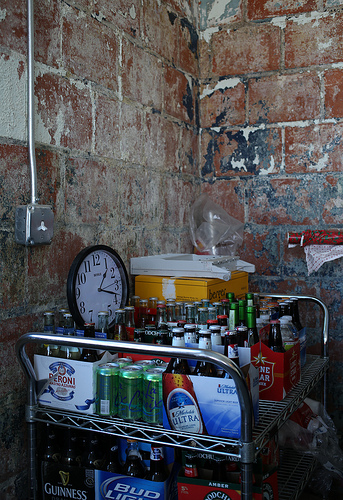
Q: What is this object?
A: Clock.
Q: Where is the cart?
A: In the corner.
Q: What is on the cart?
A: Beer.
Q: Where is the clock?
A: On the cart behind the beer.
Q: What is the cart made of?
A: Metal.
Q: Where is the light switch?
A: On the wall.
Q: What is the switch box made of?
A: Metal.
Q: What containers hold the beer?
A: Cans and bottles.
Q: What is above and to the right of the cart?
A: Wrapping paper.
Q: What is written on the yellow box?
A: Berger.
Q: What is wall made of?
A: Brick.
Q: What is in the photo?
A: Beer.